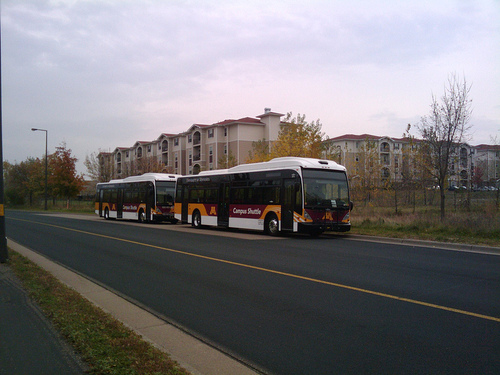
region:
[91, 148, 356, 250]
two buses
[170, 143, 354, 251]
this is a bus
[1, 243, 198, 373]
a patch of grass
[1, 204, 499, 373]
black road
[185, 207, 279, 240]
the buses have black tires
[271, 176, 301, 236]
the bus has a black door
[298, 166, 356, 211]
the bus has a big windshield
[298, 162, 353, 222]
the windshield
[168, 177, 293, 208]
the bus has many windows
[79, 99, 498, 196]
the building is brown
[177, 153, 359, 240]
Metro bus waiting for passengers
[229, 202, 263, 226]
Sign says Metro Shuttle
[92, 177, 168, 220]
Bus is black, white, orange, and purple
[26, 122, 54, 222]
Lamp post on sidewalk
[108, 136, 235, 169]
Apartment building is tan and beige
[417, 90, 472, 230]
The tree does not have leaves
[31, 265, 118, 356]
Grass on sidewalk is green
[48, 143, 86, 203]
The leaves are changing color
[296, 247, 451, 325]
Yellow line for two way street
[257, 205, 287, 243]
Front wheel on metro bus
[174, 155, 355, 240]
A bus parked on the side of the road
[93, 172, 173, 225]
A bus parked on the side of the road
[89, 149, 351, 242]
A pair of buses parked on the side of the road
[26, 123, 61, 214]
A tall street light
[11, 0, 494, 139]
a cloudy sky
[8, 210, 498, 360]
an asphalt road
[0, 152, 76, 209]
a line of trees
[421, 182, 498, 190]
A line of parked cars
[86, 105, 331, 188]
A large apartment building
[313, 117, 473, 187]
A large apartment building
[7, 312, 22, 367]
path next to the road.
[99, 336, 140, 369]
grass on the ground.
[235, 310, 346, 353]
blacktop on the road.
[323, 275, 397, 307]
yellow paint on the road.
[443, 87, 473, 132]
bare limbs on trees.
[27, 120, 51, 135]
light on light post.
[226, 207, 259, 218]
writing on the bus.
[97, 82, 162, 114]
clouds in the sky.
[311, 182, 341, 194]
windshield of the bus.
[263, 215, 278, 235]
wheel on the bus.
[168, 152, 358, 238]
long white passenger bus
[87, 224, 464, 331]
yellow stripe down the middle of the road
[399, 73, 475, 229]
tree bare of leaves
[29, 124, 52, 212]
tall grey steel street lamp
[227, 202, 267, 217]
purple banner on side of bus stating campus shuttle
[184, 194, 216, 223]
yellow paint on side of bus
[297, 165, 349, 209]
front drivers windshield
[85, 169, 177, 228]
one bus parked behind another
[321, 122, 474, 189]
three story concrete building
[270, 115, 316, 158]
golden leaves on tree